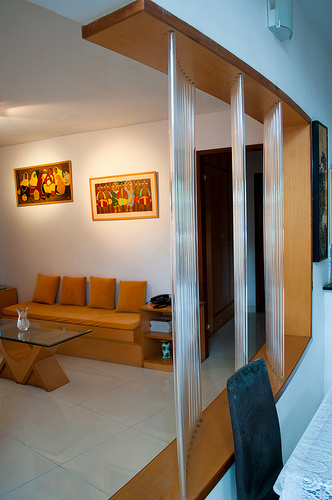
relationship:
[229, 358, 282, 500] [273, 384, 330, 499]
chair next to table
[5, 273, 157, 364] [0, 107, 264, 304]
couch against wall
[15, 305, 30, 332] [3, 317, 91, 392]
vase on top of coffee table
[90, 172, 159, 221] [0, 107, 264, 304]
picture attached to wall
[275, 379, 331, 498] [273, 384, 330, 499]
tablecloth on top of table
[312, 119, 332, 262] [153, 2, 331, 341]
picture mounted on wall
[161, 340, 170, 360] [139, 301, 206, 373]
candle under side table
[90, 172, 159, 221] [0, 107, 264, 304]
picture hanging on wall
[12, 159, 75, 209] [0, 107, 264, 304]
picture hanging on wall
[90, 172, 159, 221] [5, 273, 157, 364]
picture above couch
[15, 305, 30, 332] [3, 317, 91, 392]
vase on top f coffee table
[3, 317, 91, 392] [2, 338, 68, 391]
coffee table has base